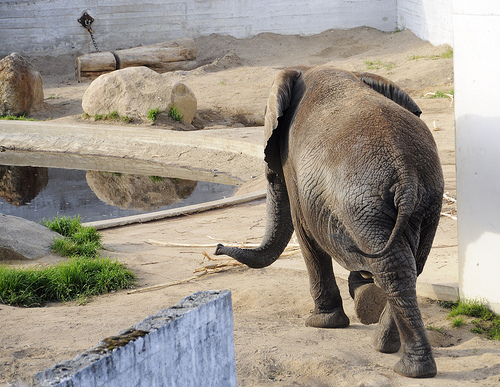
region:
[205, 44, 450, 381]
The elephant is walking.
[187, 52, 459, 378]
The elephant is gray.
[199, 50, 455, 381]
The elephant is dry.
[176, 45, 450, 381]
The elephant's skin is wrinkly.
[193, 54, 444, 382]
The elephant has a long trunk.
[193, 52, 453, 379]
The elephant has four legs.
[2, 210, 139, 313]
The grass is green.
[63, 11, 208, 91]
The tree trunk is chained.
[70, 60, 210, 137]
The rock is large.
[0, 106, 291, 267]
The pond has water in it.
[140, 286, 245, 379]
old white wall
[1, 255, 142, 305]
patch of grass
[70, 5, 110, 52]
a chain fixed to the wall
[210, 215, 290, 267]
the trunk of an elephant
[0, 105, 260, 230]
pool of water for an animal in a zoo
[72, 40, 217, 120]
log and a rock in the animal's pen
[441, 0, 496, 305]
the side of a building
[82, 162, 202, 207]
reflection of a rock in the water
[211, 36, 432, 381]
an elephant lumbers forward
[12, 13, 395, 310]
the animal's living area in a zoo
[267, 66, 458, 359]
Gray baby elephant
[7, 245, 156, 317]
Patch of grass in zoo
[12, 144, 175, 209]
Pond of water in elephant pin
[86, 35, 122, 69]
Chain around a log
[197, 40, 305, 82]
Sand in a elephant pin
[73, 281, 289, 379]
Stone wall in a zoo pin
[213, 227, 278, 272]
Elephant with a trunk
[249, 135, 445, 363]
Elephant walking forward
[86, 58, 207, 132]
Rock in a zoo pin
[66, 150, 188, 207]
Shadow of rock on water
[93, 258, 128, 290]
patch of green grass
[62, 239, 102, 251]
patch of green grass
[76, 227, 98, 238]
patch of green grass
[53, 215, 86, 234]
patch of green grass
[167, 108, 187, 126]
patch of green grass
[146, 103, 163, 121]
patch of green grass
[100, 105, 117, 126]
patch of green grass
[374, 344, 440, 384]
grey leg of elephant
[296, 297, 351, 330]
grey leg of elephant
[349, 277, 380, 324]
grey leg of elephant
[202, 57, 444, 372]
an elephant walking towards the water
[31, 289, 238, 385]
part of a white wall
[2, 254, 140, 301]
the grass close to the water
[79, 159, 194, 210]
the reflection of the rock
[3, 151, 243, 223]
the water in the little pool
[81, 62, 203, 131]
the rock next to the water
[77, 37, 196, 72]
a log on the ground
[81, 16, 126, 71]
a chain connected to the log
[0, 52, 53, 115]
a light brown rock on the ground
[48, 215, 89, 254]
some more grass on the ground